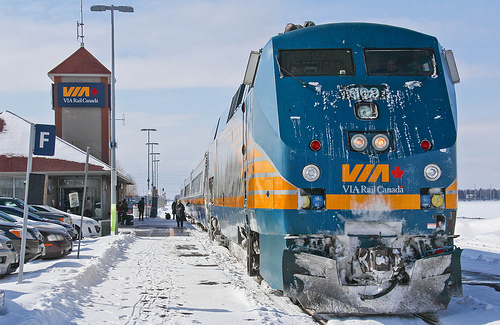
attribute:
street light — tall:
[89, 0, 133, 240]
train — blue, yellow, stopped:
[175, 9, 460, 319]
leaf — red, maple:
[390, 164, 404, 181]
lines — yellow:
[178, 111, 463, 231]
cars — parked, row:
[0, 189, 105, 291]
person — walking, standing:
[173, 200, 189, 225]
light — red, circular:
[308, 136, 322, 153]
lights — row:
[90, 2, 185, 163]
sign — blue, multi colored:
[52, 83, 107, 109]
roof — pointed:
[47, 44, 121, 75]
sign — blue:
[28, 120, 61, 152]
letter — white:
[38, 130, 48, 152]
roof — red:
[0, 94, 117, 181]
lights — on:
[348, 135, 398, 154]